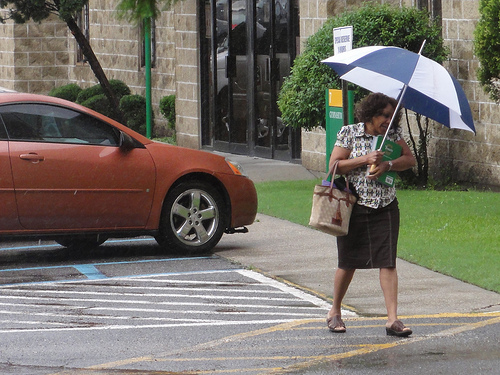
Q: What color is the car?
A: Orange.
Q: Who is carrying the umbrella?
A: The woman.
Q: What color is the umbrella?
A: Blue and white.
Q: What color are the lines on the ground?
A: Blue white and yellow.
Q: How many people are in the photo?
A: 1.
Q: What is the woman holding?
A: An umbrella, book, and purse.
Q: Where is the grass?
A: To the right middle of the picture.